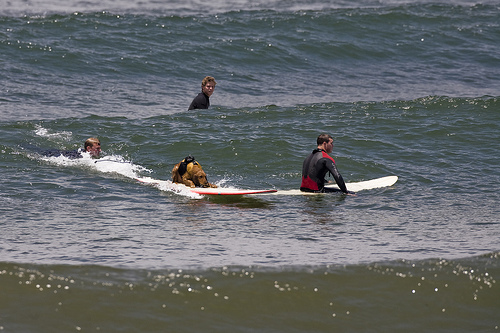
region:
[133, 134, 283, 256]
the dog is surfing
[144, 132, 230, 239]
the dog is surfing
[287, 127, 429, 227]
man wears black and red wetsuit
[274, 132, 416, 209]
man sits on white surfboard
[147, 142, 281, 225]
dog sits on surfboard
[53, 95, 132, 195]
one man neck-deep in water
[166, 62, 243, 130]
one man wearing black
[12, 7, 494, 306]
ripples in the water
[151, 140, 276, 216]
golden retriever wears black life preserver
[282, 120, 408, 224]
man in black and red wet suit faces right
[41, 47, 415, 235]
three men and a dog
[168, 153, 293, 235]
edges of the surfboard are orange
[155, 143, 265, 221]
dog riding a surfboard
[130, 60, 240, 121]
man looking at camera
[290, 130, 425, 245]
man sitting on surboard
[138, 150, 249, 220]
surfing dog in water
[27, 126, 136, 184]
man lying on surfboard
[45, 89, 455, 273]
surfers waiting for waves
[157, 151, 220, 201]
large brown dog in water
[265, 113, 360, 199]
man in red and black wetsuit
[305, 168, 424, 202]
sitting on white surfboard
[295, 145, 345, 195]
a red and black wetsuit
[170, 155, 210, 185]
a dog on a surfboard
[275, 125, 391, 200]
a white surfboard under a man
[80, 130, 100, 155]
a head poking out of the water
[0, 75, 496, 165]
a wave on the water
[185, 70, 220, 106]
a black wetsuit on a man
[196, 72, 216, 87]
dry hair on a man's head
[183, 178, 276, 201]
a red and white surfboard under a dog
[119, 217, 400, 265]
light shining on the water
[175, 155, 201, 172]
a yellow and black vest on a dog